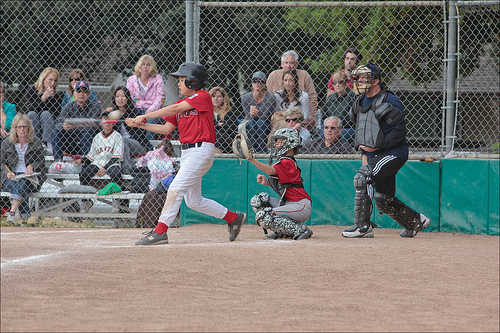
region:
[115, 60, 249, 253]
Young baseball player batting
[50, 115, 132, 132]
Black and red baseball bat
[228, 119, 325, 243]
Young baseball catcher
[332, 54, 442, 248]
Older baseball umpire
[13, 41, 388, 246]
Families of the baseball players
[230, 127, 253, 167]
White and black catcher's glove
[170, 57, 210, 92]
Black baseball helmet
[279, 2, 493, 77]
Green tree hanging down in the background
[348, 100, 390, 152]
Black and gray umpire vest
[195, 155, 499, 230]
Soft green padding around the fence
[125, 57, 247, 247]
Young boy batter at baseball game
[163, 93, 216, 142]
Red jersey on boy baseball player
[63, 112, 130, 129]
Baseball bat held by young boy batter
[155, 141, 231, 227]
White pants on baseball batter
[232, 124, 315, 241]
Catcher behind batter at baseball game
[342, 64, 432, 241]
Home plate umpire at baseball game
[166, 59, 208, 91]
Black helmet on baseball batter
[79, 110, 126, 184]
Spectator in white jersey at baseball game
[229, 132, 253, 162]
Mitt used by catcher in baseball game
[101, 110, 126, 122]
Baseball being swung at in game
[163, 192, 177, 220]
left leg of a boy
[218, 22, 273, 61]
part of a perimeter wall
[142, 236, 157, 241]
left shoe of a boy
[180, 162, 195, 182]
part of a white trouser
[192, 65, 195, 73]
section of a black helmet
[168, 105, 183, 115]
elbow of a boy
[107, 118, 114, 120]
section of a baseball bat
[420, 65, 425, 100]
section of a perimeter wall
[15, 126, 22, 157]
a lady in the fans section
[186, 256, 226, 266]
section of a baseball court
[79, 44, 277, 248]
a baseball player swinging his bat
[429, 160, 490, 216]
plastic green covering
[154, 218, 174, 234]
a red sock on an ankle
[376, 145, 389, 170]
white stripes on pants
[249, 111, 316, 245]
a player wearing a helmet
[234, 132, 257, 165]
a hand holding a mitt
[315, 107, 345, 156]
a man wearing sunglasses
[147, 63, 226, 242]
a player wearing a black helmet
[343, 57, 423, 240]
an umpire wearing shin guards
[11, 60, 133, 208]
spectators behind the fence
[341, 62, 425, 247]
the baseball referee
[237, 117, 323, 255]
the baseball catcher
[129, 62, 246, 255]
the player at bat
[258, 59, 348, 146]
spectators behind the fence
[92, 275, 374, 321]
dirt area on baseball field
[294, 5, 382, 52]
tree behind the fence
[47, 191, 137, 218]
part of baseball bleacher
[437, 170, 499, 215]
padding on side of stadium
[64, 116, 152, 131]
hands holding baseball bat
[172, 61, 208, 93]
baseball helmet on player